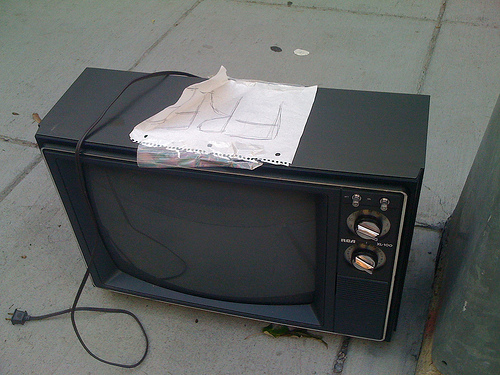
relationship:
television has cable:
[26, 58, 431, 348] [0, 272, 155, 372]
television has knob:
[26, 58, 431, 348] [338, 240, 388, 276]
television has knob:
[26, 58, 431, 348] [348, 209, 387, 242]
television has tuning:
[26, 58, 431, 348] [373, 193, 393, 213]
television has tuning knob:
[26, 58, 431, 348] [349, 189, 364, 209]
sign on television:
[126, 63, 319, 162] [35, 58, 431, 343]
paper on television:
[122, 59, 323, 168] [35, 58, 431, 343]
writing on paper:
[159, 87, 289, 147] [122, 59, 323, 168]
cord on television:
[1, 68, 201, 372] [35, 58, 431, 343]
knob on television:
[338, 240, 388, 276] [35, 58, 431, 343]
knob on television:
[348, 209, 387, 242] [35, 58, 431, 343]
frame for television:
[30, 64, 431, 193] [35, 58, 431, 343]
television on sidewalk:
[35, 58, 431, 343] [2, 3, 483, 373]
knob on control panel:
[338, 240, 388, 276] [330, 188, 404, 341]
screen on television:
[68, 154, 321, 328] [35, 58, 431, 343]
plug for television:
[2, 305, 30, 329] [35, 58, 431, 343]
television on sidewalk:
[26, 58, 431, 348] [2, 3, 483, 373]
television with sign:
[26, 58, 431, 348] [126, 63, 319, 162]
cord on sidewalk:
[1, 68, 201, 372] [2, 3, 483, 373]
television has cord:
[26, 58, 431, 348] [3, 38, 208, 368]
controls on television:
[342, 191, 399, 280] [26, 58, 431, 348]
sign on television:
[126, 63, 319, 162] [26, 58, 431, 348]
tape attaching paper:
[132, 143, 262, 176] [127, 65, 324, 168]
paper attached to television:
[127, 65, 324, 168] [26, 58, 431, 348]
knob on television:
[348, 209, 387, 242] [26, 58, 431, 348]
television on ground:
[26, 58, 431, 348] [5, 0, 495, 373]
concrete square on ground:
[129, 3, 438, 67] [5, 0, 495, 373]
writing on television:
[334, 232, 362, 254] [26, 58, 431, 348]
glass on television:
[82, 159, 322, 299] [26, 58, 431, 348]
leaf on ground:
[256, 318, 328, 348] [5, 0, 495, 373]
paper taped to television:
[122, 59, 323, 168] [26, 58, 431, 348]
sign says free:
[126, 63, 319, 162] [141, 83, 291, 143]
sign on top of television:
[126, 63, 319, 162] [26, 58, 431, 348]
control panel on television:
[330, 188, 404, 341] [26, 58, 431, 348]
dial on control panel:
[345, 209, 386, 245] [330, 188, 404, 341]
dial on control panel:
[349, 242, 384, 275] [330, 188, 404, 341]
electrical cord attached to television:
[2, 65, 198, 373] [26, 58, 431, 348]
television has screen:
[26, 58, 431, 348] [97, 160, 327, 308]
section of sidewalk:
[114, 3, 455, 93] [2, 3, 483, 373]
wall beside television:
[423, 105, 496, 370] [26, 58, 431, 348]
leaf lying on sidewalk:
[256, 318, 328, 348] [2, 3, 483, 373]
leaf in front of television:
[256, 318, 328, 348] [26, 58, 431, 348]